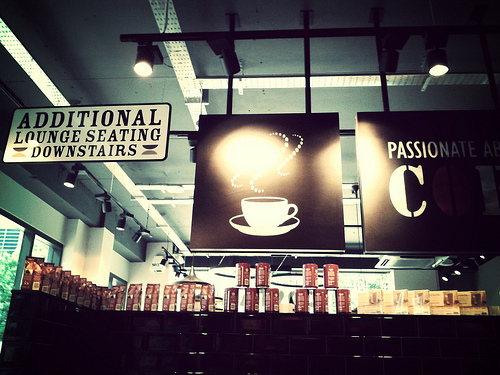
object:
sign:
[358, 106, 496, 255]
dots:
[230, 131, 287, 192]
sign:
[187, 113, 346, 249]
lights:
[114, 205, 132, 235]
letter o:
[27, 130, 33, 143]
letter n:
[118, 105, 131, 128]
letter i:
[92, 107, 99, 129]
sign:
[4, 102, 174, 165]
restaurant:
[0, 5, 500, 373]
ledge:
[0, 289, 483, 375]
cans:
[222, 261, 282, 314]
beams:
[0, 25, 64, 112]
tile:
[108, 320, 475, 372]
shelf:
[109, 307, 476, 322]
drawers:
[109, 311, 500, 375]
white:
[84, 255, 97, 270]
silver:
[347, 351, 386, 375]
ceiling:
[49, 0, 500, 264]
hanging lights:
[299, 36, 316, 114]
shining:
[184, 186, 218, 204]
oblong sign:
[2, 103, 173, 164]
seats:
[55, 342, 160, 375]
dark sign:
[357, 115, 490, 253]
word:
[387, 162, 426, 220]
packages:
[349, 284, 486, 316]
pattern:
[372, 313, 421, 362]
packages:
[98, 279, 207, 314]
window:
[1, 211, 64, 350]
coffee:
[141, 337, 201, 366]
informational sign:
[0, 102, 167, 165]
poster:
[187, 112, 344, 254]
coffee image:
[227, 127, 310, 236]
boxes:
[356, 286, 486, 313]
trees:
[0, 253, 15, 325]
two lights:
[128, 45, 450, 82]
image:
[184, 111, 344, 258]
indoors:
[0, 0, 500, 375]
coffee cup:
[223, 191, 304, 238]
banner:
[185, 110, 343, 264]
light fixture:
[133, 40, 153, 81]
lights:
[62, 167, 80, 188]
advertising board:
[354, 0, 497, 258]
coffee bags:
[21, 257, 216, 311]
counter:
[0, 290, 497, 375]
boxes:
[223, 260, 353, 317]